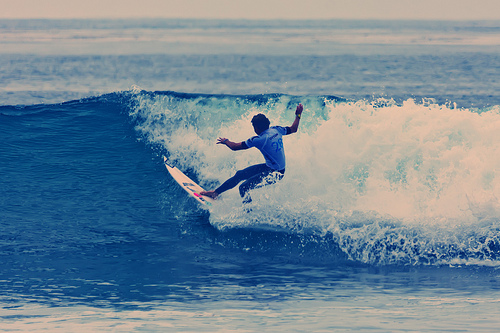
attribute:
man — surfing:
[197, 105, 303, 216]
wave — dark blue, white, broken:
[5, 74, 499, 286]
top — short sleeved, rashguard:
[243, 125, 290, 171]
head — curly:
[251, 114, 272, 132]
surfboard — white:
[161, 153, 214, 207]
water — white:
[316, 99, 499, 256]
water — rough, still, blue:
[2, 19, 499, 331]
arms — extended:
[211, 101, 311, 152]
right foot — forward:
[197, 189, 221, 202]